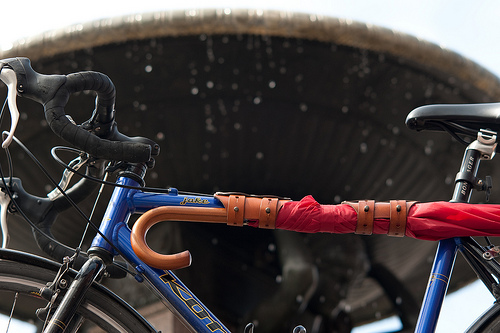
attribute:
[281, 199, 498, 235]
cloth — red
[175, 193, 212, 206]
letters — black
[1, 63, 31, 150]
brake handle — silver brake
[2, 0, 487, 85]
sky — white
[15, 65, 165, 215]
handle — wooden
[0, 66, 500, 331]
tunnel — dark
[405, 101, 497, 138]
seat — black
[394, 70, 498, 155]
seat — black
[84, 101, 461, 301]
bicycle — blue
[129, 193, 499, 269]
umbrella — brown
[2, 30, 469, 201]
rain — falling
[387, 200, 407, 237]
strap — brown